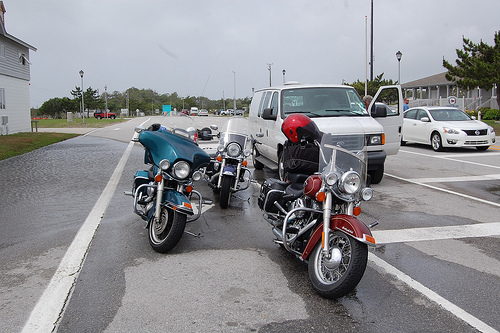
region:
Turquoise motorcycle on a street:
[128, 112, 215, 249]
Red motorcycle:
[251, 114, 378, 296]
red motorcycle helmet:
[285, 110, 322, 143]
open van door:
[369, 85, 406, 155]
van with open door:
[248, 90, 405, 182]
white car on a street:
[399, 101, 493, 154]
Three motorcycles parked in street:
[140, 120, 376, 297]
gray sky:
[0, 10, 491, 81]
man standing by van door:
[355, 91, 386, 117]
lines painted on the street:
[418, 148, 493, 305]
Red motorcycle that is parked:
[262, 139, 381, 303]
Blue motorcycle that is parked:
[132, 120, 209, 254]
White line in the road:
[17, 213, 101, 331]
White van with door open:
[246, 84, 405, 179]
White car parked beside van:
[403, 101, 498, 161]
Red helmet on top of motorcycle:
[282, 108, 322, 149]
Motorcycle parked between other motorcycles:
[208, 118, 257, 214]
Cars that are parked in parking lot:
[172, 100, 245, 119]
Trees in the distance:
[68, 80, 160, 116]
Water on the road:
[34, 147, 102, 222]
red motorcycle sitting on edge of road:
[254, 137, 381, 299]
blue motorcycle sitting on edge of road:
[126, 116, 203, 251]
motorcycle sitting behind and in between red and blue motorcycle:
[206, 116, 258, 211]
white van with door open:
[240, 88, 402, 183]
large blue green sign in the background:
[159, 100, 174, 115]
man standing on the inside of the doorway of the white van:
[360, 92, 386, 112]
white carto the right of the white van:
[400, 100, 495, 150]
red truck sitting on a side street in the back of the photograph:
[92, 101, 113, 119]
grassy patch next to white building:
[0, 131, 80, 161]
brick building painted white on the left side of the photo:
[2, 90, 36, 135]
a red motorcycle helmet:
[277, 113, 312, 143]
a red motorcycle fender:
[271, 210, 401, 259]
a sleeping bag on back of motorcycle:
[283, 141, 322, 173]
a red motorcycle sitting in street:
[268, 115, 389, 306]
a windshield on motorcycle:
[298, 123, 371, 307]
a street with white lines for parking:
[380, 151, 499, 294]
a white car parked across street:
[399, 105, 496, 161]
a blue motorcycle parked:
[125, 122, 207, 257]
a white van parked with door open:
[251, 71, 410, 186]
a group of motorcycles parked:
[125, 85, 380, 315]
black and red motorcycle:
[265, 114, 372, 301]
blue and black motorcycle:
[132, 112, 208, 250]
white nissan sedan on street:
[400, 105, 493, 150]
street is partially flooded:
[1, 130, 181, 330]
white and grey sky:
[1, 2, 498, 102]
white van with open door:
[252, 86, 394, 184]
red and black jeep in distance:
[93, 107, 118, 119]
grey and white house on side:
[1, 1, 36, 130]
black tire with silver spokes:
[312, 227, 367, 293]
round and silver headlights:
[157, 158, 202, 180]